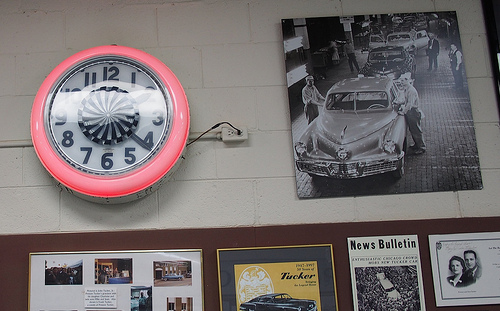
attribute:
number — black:
[59, 128, 73, 147]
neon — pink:
[30, 42, 192, 202]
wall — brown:
[0, 212, 498, 309]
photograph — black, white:
[256, 3, 493, 196]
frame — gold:
[204, 234, 343, 309]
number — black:
[103, 65, 119, 86]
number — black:
[98, 153, 115, 173]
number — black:
[75, 143, 93, 175]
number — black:
[55, 129, 74, 154]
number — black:
[120, 141, 137, 171]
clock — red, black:
[28, 33, 199, 224]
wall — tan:
[7, 5, 496, 227]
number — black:
[101, 65, 123, 82]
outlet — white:
[209, 121, 261, 151]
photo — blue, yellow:
[211, 237, 344, 309]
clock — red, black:
[31, 33, 191, 200]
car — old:
[289, 72, 431, 188]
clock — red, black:
[27, 46, 190, 200]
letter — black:
[349, 240, 356, 251]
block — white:
[164, 174, 288, 262]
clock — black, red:
[22, 30, 209, 210]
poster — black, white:
[278, 9, 484, 200]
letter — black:
[373, 232, 390, 259]